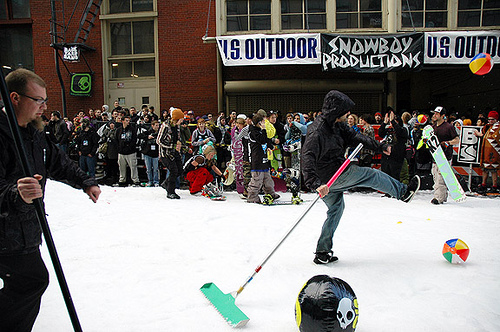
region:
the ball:
[419, 211, 481, 263]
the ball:
[384, 202, 494, 291]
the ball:
[358, 213, 467, 259]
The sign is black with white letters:
[323, 27, 419, 84]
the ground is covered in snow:
[50, 183, 497, 317]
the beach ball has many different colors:
[429, 230, 497, 285]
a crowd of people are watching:
[31, 76, 498, 234]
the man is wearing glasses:
[12, 81, 57, 115]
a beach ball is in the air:
[450, 35, 495, 95]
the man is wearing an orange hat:
[151, 97, 188, 127]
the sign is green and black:
[55, 61, 114, 114]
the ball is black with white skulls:
[283, 261, 358, 325]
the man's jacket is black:
[302, 89, 347, 193]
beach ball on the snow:
[425, 236, 483, 271]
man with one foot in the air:
[296, 75, 433, 273]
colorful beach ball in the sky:
[462, 46, 499, 86]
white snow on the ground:
[117, 208, 216, 260]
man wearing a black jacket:
[288, 87, 421, 264]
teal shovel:
[197, 274, 262, 330]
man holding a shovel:
[299, 70, 424, 270]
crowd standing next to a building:
[99, 87, 314, 204]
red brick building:
[167, 16, 202, 96]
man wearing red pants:
[181, 145, 232, 210]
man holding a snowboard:
[420, 121, 482, 203]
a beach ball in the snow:
[430, 236, 477, 272]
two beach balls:
[433, 56, 498, 273]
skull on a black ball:
[297, 272, 377, 329]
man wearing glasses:
[13, 84, 67, 121]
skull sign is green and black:
[65, 56, 112, 101]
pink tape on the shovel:
[310, 153, 375, 205]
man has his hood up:
[277, 81, 369, 141]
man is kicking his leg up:
[332, 145, 461, 239]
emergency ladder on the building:
[40, 5, 107, 62]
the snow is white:
[104, 181, 194, 301]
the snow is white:
[125, 212, 203, 329]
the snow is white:
[110, 148, 227, 289]